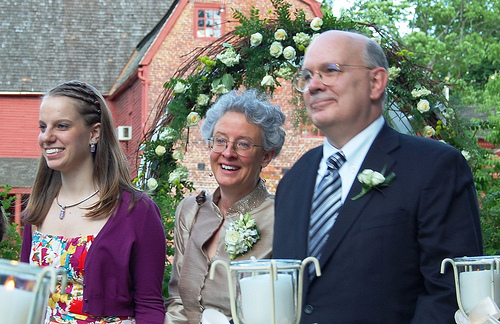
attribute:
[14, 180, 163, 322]
sweater — purple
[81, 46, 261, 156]
wall — red, brick, end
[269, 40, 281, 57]
flower — white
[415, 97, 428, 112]
flower — white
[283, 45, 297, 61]
flower — white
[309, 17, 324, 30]
flower — white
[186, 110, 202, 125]
flower — white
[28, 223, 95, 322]
dress — brightly colored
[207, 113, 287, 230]
woman — old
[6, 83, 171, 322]
woman — young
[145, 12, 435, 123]
wreath — rose